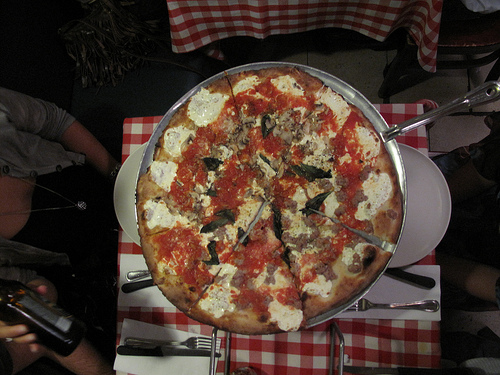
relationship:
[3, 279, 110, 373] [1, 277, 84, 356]
hand holding beer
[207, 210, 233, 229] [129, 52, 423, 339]
mushroom on pizza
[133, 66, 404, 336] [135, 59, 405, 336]
pizza on a cup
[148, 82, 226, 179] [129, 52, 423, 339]
melted cheese on a pizza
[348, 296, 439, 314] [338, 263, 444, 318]
fork on a napkin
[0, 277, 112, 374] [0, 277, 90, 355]
person holding cell phone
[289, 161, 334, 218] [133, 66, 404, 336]
spinach on top of a pizza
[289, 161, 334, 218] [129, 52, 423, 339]
spinach on top of a pizza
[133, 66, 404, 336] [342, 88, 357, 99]
pizza on pan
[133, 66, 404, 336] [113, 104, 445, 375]
pizza on cloth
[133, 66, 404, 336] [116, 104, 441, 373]
pizza on table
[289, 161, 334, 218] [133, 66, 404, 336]
spinach on pizza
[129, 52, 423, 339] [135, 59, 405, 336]
pizza on a cup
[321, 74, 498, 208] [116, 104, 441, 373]
silverware on a table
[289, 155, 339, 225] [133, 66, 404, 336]
spinach on top of a pizza